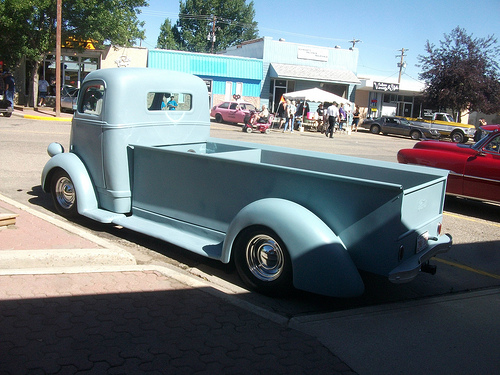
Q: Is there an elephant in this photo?
A: No, there are no elephants.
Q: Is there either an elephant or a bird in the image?
A: No, there are no elephants or birds.